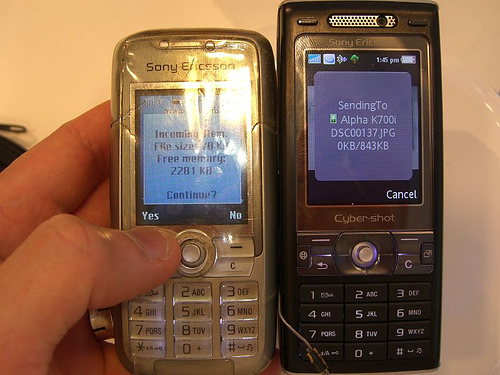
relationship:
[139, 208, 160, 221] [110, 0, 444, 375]
yes on phones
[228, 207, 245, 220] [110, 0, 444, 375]
no on phones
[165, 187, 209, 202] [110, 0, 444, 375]
continue on phones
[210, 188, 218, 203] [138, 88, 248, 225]
question mark on screen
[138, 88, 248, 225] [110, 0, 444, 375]
screen of phones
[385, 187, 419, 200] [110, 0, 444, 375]
cancel icon on phones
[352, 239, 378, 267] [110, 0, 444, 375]
button on phones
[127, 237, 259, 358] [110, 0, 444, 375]
buttons on phones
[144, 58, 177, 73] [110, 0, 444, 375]
sony on phones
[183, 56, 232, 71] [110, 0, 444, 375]
ecrisson on phones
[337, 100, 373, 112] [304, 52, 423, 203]
sending on screen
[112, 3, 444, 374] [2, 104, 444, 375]
phones in hand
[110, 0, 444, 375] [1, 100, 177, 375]
phones in hand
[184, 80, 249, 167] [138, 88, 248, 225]
glare on screen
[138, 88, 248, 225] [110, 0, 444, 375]
screen on phones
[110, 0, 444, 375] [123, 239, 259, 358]
phones has buttons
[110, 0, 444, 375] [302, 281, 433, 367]
phones has keypad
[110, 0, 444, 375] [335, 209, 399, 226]
phones says cyber-shot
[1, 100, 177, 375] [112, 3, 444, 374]
hand holding phones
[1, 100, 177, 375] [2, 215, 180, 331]
hand has thumb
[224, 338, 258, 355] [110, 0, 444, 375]
key on phones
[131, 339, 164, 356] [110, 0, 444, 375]
key on phones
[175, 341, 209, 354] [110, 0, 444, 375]
key on phones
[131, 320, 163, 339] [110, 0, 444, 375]
key on phones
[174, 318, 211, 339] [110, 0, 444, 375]
key on phones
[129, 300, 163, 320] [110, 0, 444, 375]
key on phones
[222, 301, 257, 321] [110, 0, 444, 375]
key on phones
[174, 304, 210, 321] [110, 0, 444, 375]
key on phones